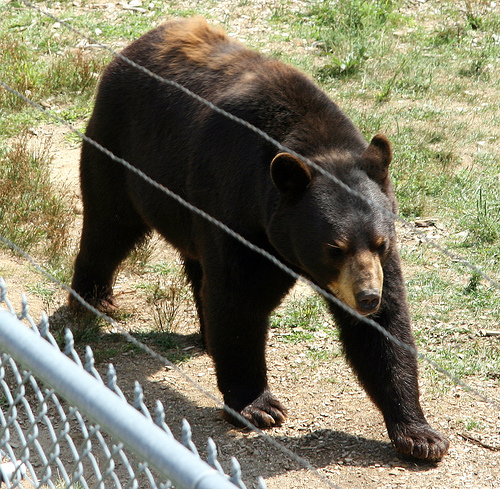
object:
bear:
[67, 16, 450, 467]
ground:
[0, 0, 500, 489]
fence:
[7, 289, 258, 489]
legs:
[204, 279, 289, 428]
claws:
[396, 434, 452, 456]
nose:
[358, 290, 381, 309]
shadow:
[0, 306, 402, 489]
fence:
[1, 9, 261, 253]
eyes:
[321, 232, 342, 249]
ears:
[271, 151, 312, 195]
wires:
[0, 84, 497, 411]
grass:
[280, 296, 329, 343]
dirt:
[167, 360, 211, 414]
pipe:
[1, 312, 247, 486]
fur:
[159, 21, 215, 64]